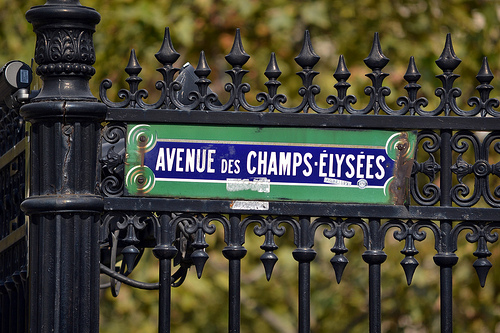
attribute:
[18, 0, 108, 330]
fence post — old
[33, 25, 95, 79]
decoration — nice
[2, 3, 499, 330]
fence — iron, metal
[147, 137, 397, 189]
sign — french, blue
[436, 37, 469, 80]
spike — triangular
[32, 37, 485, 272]
fence — black, metal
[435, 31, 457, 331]
spoke — metal, black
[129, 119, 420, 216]
sign — rusting, white, green, blue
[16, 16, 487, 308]
fence — iron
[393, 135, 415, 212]
rust — brown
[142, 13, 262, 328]
fence — decorative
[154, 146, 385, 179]
letters — white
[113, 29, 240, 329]
fence — old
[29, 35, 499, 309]
fence — iron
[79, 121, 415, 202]
sign — green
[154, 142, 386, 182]
letters — white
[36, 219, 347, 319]
fence — metal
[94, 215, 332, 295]
fence — metal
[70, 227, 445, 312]
fence — metal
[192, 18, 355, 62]
foliage — green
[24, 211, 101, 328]
pole — black, metal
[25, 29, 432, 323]
fence — iron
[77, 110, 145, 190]
camera — newer